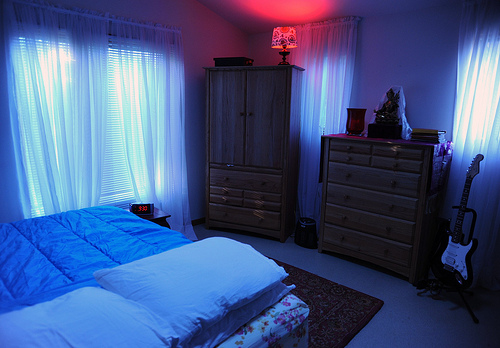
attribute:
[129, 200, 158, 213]
clock — digital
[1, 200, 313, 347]
bed — made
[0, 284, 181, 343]
pillow — white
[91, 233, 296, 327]
pillow — white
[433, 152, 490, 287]
guitar — electric, black, white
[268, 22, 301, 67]
lamp — emitting, red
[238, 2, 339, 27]
light — red, orange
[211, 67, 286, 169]
doors — closed, wardrobe's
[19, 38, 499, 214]
light — coming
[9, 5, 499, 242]
drapes — see-through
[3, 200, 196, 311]
comforter — blue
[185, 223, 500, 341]
carpet — brown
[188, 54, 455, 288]
cabinets — wooden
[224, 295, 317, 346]
sheet — floral design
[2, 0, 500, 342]
room — illuminated, illuminated blue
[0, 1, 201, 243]
curtains — white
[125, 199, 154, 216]
alarm clock — digital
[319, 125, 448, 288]
dresser — wooden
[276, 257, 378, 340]
design — oriental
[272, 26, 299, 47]
shade — patterned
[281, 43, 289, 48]
lightbulb — red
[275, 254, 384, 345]
floor rug — oriental, red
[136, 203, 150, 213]
display — red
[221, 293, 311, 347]
sheets — floral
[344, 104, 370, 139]
vase — red, glass, upright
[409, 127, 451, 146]
stack — books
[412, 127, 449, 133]
book — yellow